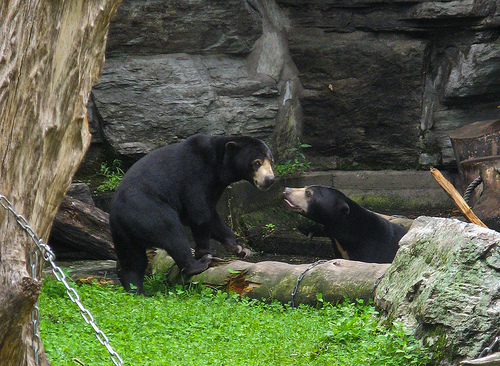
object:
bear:
[106, 132, 277, 295]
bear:
[279, 182, 410, 264]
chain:
[0, 193, 135, 364]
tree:
[0, 0, 121, 365]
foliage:
[38, 288, 429, 366]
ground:
[31, 206, 500, 365]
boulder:
[372, 213, 499, 365]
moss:
[438, 245, 475, 307]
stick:
[427, 166, 489, 229]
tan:
[258, 159, 274, 177]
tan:
[283, 185, 308, 213]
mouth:
[281, 191, 306, 215]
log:
[143, 247, 392, 308]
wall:
[81, 0, 500, 171]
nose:
[264, 175, 276, 184]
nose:
[282, 186, 292, 196]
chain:
[290, 258, 328, 309]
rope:
[463, 171, 484, 203]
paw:
[227, 238, 252, 260]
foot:
[181, 258, 212, 277]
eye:
[253, 160, 262, 167]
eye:
[306, 191, 311, 197]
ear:
[224, 140, 239, 148]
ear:
[339, 202, 351, 216]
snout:
[252, 170, 277, 193]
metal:
[7, 204, 29, 225]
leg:
[132, 199, 212, 275]